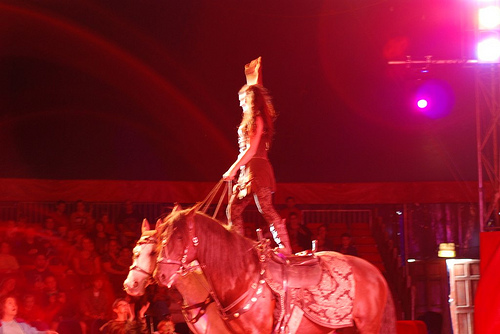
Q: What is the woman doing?
A: Standing on horses.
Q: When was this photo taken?
A: During a performance.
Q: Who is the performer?
A: The woman.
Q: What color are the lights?
A: Red.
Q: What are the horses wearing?
A: Saddles.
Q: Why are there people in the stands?
A: To see the performance.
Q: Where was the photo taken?
A: An arena.